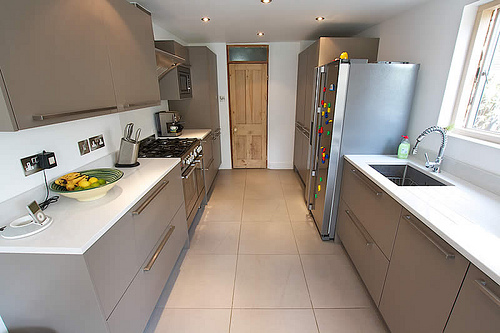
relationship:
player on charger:
[24, 197, 54, 232] [36, 144, 67, 176]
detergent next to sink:
[393, 131, 411, 166] [375, 135, 415, 171]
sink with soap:
[335, 147, 469, 194] [387, 161, 421, 180]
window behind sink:
[435, 15, 499, 162] [335, 147, 469, 194]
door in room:
[217, 47, 271, 193] [62, 0, 494, 308]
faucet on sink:
[400, 124, 461, 170] [335, 147, 469, 194]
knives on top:
[116, 121, 149, 144] [117, 128, 149, 142]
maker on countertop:
[144, 98, 208, 148] [144, 122, 218, 143]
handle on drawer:
[131, 172, 174, 227] [69, 142, 202, 303]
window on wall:
[435, 15, 499, 162] [401, 9, 481, 114]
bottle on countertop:
[397, 132, 420, 161] [348, 140, 487, 253]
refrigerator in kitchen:
[306, 51, 408, 231] [62, 0, 494, 308]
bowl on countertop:
[43, 166, 128, 202] [144, 122, 218, 143]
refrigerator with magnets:
[306, 51, 408, 231] [315, 94, 333, 182]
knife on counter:
[133, 128, 144, 142] [54, 159, 171, 256]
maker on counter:
[144, 98, 208, 148] [54, 159, 171, 256]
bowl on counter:
[43, 166, 128, 202] [54, 159, 171, 256]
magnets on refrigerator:
[315, 94, 333, 182] [306, 51, 408, 231]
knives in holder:
[116, 121, 149, 144] [118, 139, 142, 175]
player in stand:
[24, 197, 54, 232] [19, 217, 45, 232]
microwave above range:
[154, 46, 219, 117] [173, 105, 229, 120]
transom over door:
[223, 39, 269, 65] [217, 47, 271, 193]